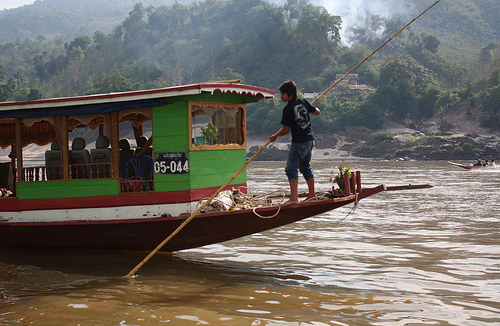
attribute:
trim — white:
[203, 84, 265, 106]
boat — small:
[1, 75, 391, 260]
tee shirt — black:
[274, 97, 318, 139]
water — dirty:
[0, 160, 499, 324]